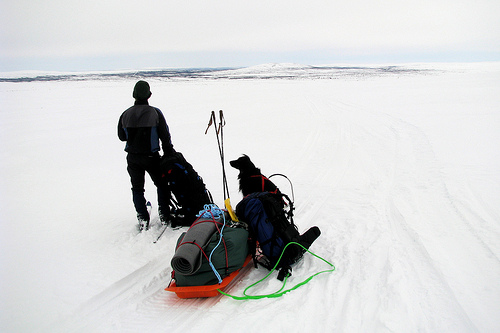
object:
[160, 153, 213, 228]
backpack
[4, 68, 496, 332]
field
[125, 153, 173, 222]
pants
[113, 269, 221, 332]
tracks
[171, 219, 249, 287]
backpack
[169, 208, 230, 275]
mat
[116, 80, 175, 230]
man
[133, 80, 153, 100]
hat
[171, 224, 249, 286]
sleeping bag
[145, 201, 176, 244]
skis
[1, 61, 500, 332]
snow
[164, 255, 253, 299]
chair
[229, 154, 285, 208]
dog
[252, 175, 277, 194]
strap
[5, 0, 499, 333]
day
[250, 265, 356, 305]
string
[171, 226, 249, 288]
bags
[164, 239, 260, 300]
sled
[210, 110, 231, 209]
poles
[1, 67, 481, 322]
ground